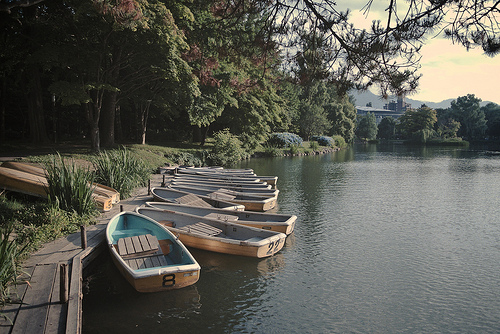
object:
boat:
[107, 206, 202, 293]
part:
[162, 271, 180, 288]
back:
[136, 267, 201, 294]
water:
[82, 150, 499, 333]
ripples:
[161, 270, 293, 333]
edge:
[64, 236, 108, 334]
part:
[343, 169, 466, 252]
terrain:
[0, 125, 232, 286]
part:
[0, 149, 107, 210]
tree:
[1, 4, 194, 153]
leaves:
[168, 33, 175, 46]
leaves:
[111, 3, 123, 16]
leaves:
[52, 23, 66, 33]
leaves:
[1, 8, 18, 18]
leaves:
[172, 72, 181, 82]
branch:
[110, 34, 125, 82]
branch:
[73, 45, 94, 88]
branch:
[119, 70, 149, 85]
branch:
[14, 36, 50, 96]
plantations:
[1, 214, 30, 293]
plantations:
[41, 149, 92, 230]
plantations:
[16, 198, 66, 250]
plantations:
[85, 155, 129, 198]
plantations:
[111, 149, 150, 185]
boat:
[133, 206, 286, 258]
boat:
[150, 184, 245, 212]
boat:
[162, 180, 279, 212]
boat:
[167, 175, 272, 190]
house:
[354, 104, 405, 120]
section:
[370, 108, 377, 110]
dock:
[0, 150, 179, 329]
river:
[74, 137, 491, 334]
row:
[105, 210, 203, 295]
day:
[0, 3, 499, 332]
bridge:
[250, 145, 341, 156]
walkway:
[2, 159, 122, 211]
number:
[267, 240, 281, 257]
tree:
[120, 13, 203, 146]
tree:
[181, 11, 277, 147]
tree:
[289, 42, 329, 140]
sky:
[272, 2, 499, 104]